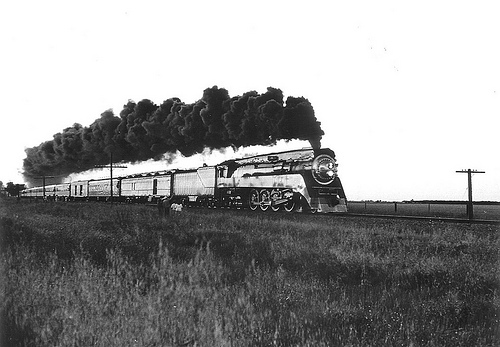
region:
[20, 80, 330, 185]
black smoke coming from a train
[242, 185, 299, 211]
the wheels on a train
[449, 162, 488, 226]
a utility pole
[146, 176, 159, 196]
an open door on a train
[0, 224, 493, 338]
a grassy field alongside the train tracks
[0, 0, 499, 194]
a bright sky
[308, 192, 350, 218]
a cattle guard on a truck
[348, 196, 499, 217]
a fence along the train tracks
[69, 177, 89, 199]
a boxcar on a train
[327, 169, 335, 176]
a headlight on a train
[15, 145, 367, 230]
A train with many cars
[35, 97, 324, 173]
The train has black smoke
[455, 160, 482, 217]
A tall power line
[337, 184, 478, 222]
A row of wooden fence posts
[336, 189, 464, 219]
The fence posts are next to the tracks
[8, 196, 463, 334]
A field full of tall grass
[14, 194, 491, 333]
There is a field on either side of the tracks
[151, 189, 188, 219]
People standing by the tracks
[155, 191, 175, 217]
The people are waving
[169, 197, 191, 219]
Two people wearing white shirts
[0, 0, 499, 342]
A black and white photograph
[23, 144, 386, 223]
the train is on the tracks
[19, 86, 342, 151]
thick billowing black smoke above the train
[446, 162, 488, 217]
a pole beside the tracks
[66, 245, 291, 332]
grass growing beside the track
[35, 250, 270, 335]
the grass is tall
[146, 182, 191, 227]
people standing on the grass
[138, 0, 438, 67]
the sky is clear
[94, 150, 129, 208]
a pole beside the train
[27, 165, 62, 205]
a pole beside the train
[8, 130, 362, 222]
a train moving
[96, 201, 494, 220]
train tracks under the train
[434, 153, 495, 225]
a telephone pole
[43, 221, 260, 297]
a field of grass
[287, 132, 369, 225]
the front of the train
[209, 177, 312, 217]
the wheels of the train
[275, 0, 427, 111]
a clear white sky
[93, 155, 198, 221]
a box car of the train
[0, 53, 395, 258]
a train puffing smoke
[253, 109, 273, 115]
part of a smoke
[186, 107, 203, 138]
part of train smoke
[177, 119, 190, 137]
dark smoke in air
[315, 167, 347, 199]
front part of a train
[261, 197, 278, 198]
bottom of a train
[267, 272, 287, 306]
part of a grass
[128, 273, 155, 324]
section of a plantation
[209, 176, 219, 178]
side of a train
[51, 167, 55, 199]
body of a train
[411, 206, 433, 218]
part of the rail way